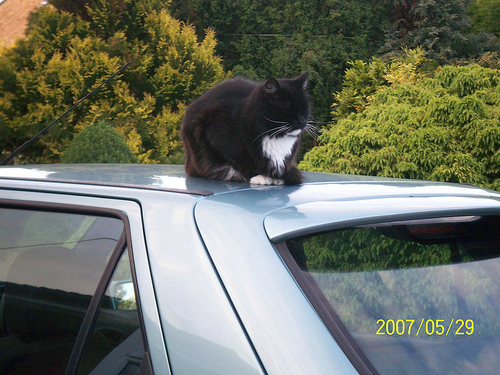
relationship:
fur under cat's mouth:
[260, 125, 305, 172] [163, 74, 320, 193]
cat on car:
[175, 66, 334, 186] [0, 161, 499, 374]